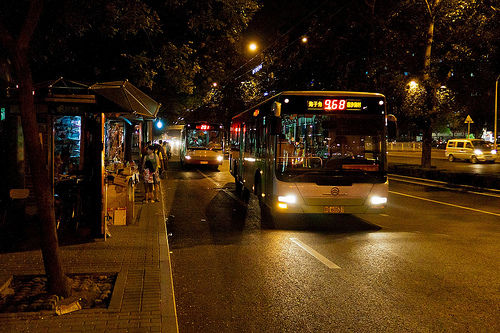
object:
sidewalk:
[1, 172, 177, 332]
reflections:
[280, 113, 330, 170]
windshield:
[279, 113, 383, 177]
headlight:
[472, 148, 480, 155]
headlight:
[488, 149, 498, 156]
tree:
[0, 0, 258, 299]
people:
[139, 146, 160, 202]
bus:
[227, 89, 397, 223]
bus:
[180, 122, 226, 170]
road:
[160, 137, 497, 329]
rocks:
[78, 275, 106, 303]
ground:
[85, 247, 455, 329]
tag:
[323, 205, 346, 214]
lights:
[369, 192, 390, 207]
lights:
[274, 194, 300, 211]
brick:
[0, 170, 161, 330]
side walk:
[0, 179, 180, 331]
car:
[444, 138, 497, 163]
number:
[319, 97, 353, 112]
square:
[2, 267, 113, 309]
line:
[287, 235, 344, 271]